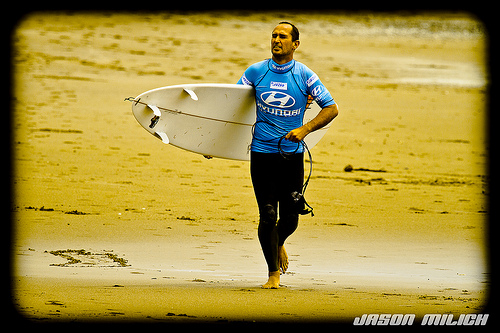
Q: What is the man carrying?
A: A surfboard.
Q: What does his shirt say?
A: Hyundai.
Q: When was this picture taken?
A: During the day.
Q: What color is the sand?
A: Tan.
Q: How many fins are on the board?
A: Three.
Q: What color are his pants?
A: Black.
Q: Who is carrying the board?
A: A man.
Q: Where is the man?
A: A beach.